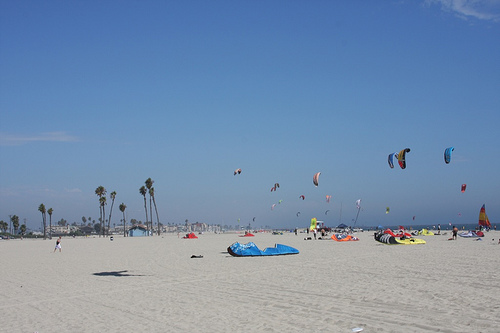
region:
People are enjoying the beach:
[26, 52, 482, 317]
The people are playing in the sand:
[26, 26, 481, 316]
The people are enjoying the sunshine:
[23, 36, 475, 317]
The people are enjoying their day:
[12, 47, 487, 319]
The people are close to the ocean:
[20, 35, 471, 306]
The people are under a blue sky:
[21, 27, 481, 297]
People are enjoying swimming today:
[23, 63, 498, 293]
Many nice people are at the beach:
[27, 46, 472, 311]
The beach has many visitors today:
[15, 53, 483, 315]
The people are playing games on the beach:
[16, 61, 478, 315]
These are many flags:
[318, 108, 487, 289]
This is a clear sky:
[172, 54, 290, 109]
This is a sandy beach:
[158, 271, 211, 326]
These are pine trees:
[95, 171, 197, 245]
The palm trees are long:
[81, 182, 183, 239]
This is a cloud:
[9, 122, 130, 186]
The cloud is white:
[26, 74, 191, 234]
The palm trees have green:
[80, 162, 145, 209]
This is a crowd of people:
[316, 222, 411, 242]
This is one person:
[28, 238, 88, 270]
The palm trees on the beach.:
[10, 178, 187, 247]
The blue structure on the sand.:
[212, 236, 316, 270]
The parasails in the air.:
[214, 148, 485, 221]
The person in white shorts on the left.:
[53, 230, 64, 250]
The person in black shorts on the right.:
[449, 226, 458, 238]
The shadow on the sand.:
[81, 258, 147, 279]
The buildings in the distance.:
[35, 207, 255, 233]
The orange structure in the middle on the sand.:
[330, 228, 359, 241]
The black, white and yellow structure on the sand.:
[372, 229, 432, 249]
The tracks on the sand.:
[17, 241, 499, 331]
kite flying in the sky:
[438, 136, 458, 171]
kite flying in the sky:
[390, 145, 417, 170]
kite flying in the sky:
[454, 177, 467, 194]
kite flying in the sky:
[385, 146, 398, 173]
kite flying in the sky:
[307, 168, 325, 188]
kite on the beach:
[221, 235, 308, 260]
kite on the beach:
[373, 230, 427, 246]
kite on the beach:
[329, 231, 361, 241]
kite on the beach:
[236, 225, 259, 241]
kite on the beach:
[179, 227, 200, 244]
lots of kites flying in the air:
[227, 147, 492, 242]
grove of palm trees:
[83, 175, 170, 242]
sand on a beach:
[40, 265, 180, 323]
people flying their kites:
[441, 218, 483, 245]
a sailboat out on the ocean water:
[467, 202, 493, 229]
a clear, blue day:
[135, 40, 327, 131]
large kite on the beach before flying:
[369, 219, 429, 254]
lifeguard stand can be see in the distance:
[308, 212, 323, 230]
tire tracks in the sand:
[292, 286, 437, 329]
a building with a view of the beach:
[40, 217, 82, 239]